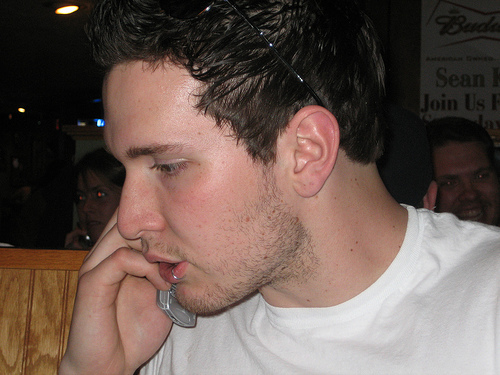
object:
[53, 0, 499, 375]
man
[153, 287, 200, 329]
cellphone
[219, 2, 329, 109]
sunglasses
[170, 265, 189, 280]
lip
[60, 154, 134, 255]
woman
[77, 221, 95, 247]
cellphone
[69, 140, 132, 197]
brown hair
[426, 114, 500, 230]
man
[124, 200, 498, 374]
shirt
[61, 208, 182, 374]
hand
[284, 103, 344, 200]
ear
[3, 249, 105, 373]
booth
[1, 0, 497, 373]
restaurant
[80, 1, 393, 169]
hair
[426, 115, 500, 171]
hair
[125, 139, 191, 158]
eyebrow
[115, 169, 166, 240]
nose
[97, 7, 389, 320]
head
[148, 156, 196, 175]
eye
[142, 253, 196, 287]
mouth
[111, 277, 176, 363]
palm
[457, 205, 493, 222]
smile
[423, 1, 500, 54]
budweiser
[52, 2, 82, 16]
ceiling light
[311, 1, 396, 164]
back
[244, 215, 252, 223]
freckles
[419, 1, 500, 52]
bowtie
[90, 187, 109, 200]
eyes